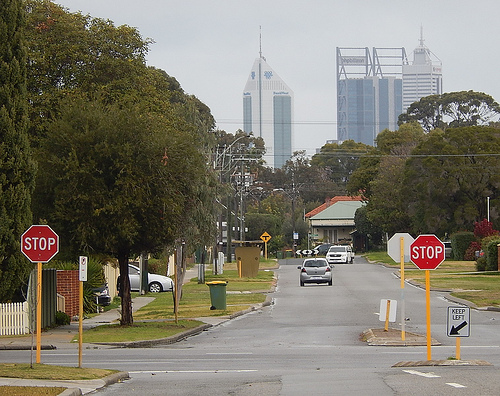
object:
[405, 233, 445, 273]
stop sign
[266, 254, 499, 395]
street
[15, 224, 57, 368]
stop sign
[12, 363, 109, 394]
sidewalk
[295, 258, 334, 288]
car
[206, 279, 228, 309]
trash can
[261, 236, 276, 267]
sign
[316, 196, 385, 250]
house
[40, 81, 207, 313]
tree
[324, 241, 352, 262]
van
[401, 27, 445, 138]
buildings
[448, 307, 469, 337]
sign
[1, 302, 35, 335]
fence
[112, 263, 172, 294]
car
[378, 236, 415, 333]
signs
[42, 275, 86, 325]
fence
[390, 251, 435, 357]
poles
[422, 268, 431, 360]
pole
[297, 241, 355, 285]
cars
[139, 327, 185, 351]
curb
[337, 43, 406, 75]
roofs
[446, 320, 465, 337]
arrow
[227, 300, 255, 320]
curb